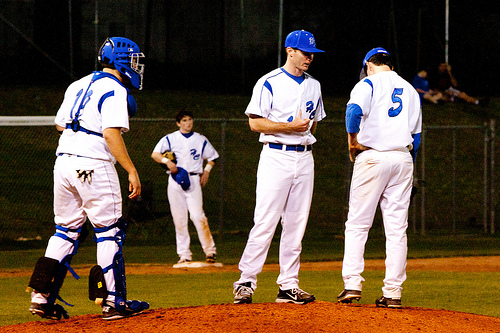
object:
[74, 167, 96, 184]
gloves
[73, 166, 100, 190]
catcher's pocket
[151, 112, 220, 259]
person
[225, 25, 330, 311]
person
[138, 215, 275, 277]
white base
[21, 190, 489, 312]
field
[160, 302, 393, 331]
dirt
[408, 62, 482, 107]
people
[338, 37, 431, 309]
person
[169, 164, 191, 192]
held hat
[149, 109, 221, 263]
waiting man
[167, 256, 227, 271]
base plate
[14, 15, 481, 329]
baseball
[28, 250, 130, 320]
shin guards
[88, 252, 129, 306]
shin guard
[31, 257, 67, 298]
shin guard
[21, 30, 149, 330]
person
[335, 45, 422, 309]
player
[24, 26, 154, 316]
catcher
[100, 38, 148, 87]
mask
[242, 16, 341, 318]
pitcher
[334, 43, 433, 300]
teammate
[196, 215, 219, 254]
dirt spot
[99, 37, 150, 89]
helmet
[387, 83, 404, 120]
5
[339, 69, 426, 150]
jersey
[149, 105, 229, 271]
player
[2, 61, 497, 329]
baseball field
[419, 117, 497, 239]
metal fence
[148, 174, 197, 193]
glove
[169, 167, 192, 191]
blue cap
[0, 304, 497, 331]
pitcher mound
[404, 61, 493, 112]
spectators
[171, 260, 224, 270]
base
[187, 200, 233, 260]
leg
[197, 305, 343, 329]
mound